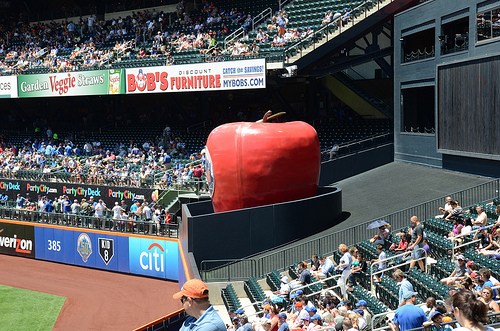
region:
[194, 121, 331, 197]
the object is red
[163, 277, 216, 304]
the hat is orange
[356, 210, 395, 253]
the umbrella is blue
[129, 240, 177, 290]
the sponsor is citi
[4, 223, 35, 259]
the sponsor is verizon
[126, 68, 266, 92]
the advert is from bobs furniture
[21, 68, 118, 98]
the advert is from garden veggie stawrs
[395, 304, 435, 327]
the shirt is blue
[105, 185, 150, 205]
partycity.com is advertised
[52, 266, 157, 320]
the ground is brown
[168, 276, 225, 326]
this is a person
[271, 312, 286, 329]
this is a person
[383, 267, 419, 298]
this is a person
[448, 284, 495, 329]
this is a person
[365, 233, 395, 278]
this is a person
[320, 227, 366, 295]
this is a person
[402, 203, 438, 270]
this is a person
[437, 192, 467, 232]
this is a person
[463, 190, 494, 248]
this is a person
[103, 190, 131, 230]
this is a person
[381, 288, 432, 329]
this is a person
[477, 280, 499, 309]
this is a person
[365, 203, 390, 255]
this is a person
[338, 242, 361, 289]
this is a person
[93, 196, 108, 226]
this is a person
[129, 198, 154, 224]
this is a person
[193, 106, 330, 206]
a red stuffed bag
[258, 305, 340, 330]
spectators with red caps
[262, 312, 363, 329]
spectators ae seated down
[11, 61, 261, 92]
brightly coloured signs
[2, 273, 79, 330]
a patch of green grass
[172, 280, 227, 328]
a man with a red cap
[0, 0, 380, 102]
the upper side of the pitch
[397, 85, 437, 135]
a closed window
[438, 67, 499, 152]
a woodenplank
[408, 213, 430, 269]
a manholdingthe railing as he walks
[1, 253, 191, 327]
warning track of the baseball field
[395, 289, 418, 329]
male baseball fan in blue cap and t-shirt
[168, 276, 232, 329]
baseball fan in blue shirt and orange cap facing the field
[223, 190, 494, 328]
fans in the slower seating area of the stadium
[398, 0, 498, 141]
glass windows protecting stadium staff and camera equipment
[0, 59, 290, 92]
advertising on the end of the upper deck seating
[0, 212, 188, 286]
advertising on the end of the lower deck seating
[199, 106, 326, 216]
giant inflated red apple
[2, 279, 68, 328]
playing surface of the baseball field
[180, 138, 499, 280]
no man's land with no seating